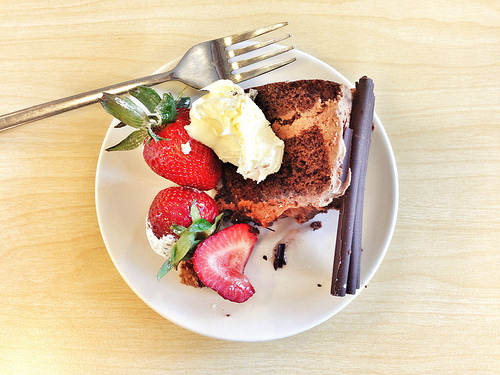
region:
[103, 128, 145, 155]
green leaf on strawberry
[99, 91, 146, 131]
green leaf on strawberry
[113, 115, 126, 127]
green leaf on strawberry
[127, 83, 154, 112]
green leaf on strawberry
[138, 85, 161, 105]
green leaf on strawberry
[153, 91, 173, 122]
green leaf on strawberry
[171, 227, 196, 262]
green leaf on strawberry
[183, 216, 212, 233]
green leaf on strawberry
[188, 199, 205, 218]
green leaf on strawberry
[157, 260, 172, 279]
green leaf on strawberry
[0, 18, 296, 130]
gray metal fork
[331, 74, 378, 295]
chocolate sticks on white plate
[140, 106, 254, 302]
three strawberries on white plate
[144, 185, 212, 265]
strawberry in the middle with Chantilly cream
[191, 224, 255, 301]
sliced strawberry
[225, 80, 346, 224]
piece of chocolate cake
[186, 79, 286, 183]
whiped cream on top of cake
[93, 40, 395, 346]
white plate where cake is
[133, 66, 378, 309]
dessert on white plate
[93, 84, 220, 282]
green strawberries leaves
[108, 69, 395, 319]
plate of healthy foods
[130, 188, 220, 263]
strawberry with cool whip on the side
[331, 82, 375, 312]
chocolate shaved into a long roll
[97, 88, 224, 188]
stem of strawberry is pulled together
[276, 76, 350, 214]
whipped mouse icing on cake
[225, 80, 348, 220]
chocolate cake with cool whip dolip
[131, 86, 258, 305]
strawberrys laid on a white plate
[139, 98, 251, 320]
strawberries laid on a white plate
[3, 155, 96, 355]
beautiful grain pattern in the wood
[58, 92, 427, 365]
white plate of fruit placed on the beautiful grain wood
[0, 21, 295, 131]
silver fork on the side of the plate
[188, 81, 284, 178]
cream cheese on top of dessert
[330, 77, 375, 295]
chocolate sticks on the side of the plate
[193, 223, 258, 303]
strawberry cut in half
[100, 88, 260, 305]
strawberries on the side of the plate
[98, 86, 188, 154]
leafy petals on top of strawberry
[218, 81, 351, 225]
a slice of cake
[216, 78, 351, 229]
square piece of dessert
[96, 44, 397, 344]
white dessert plate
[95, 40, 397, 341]
plate with chocolate dessert and strawberries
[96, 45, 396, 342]
a white plate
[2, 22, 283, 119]
a fork on the plate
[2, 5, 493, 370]
the table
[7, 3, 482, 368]
a wooden table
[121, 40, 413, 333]
a plate of dessert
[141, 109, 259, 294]
strawberries on the plate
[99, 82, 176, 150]
the leaf of the strawberry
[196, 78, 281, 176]
ice cream on the cake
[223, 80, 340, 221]
a piece of cake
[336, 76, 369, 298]
chocolate on the plate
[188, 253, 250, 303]
strawberry on the bowl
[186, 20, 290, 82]
fork in the bowl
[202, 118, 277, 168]
frosting on the cake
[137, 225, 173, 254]
frosting on the strawberry